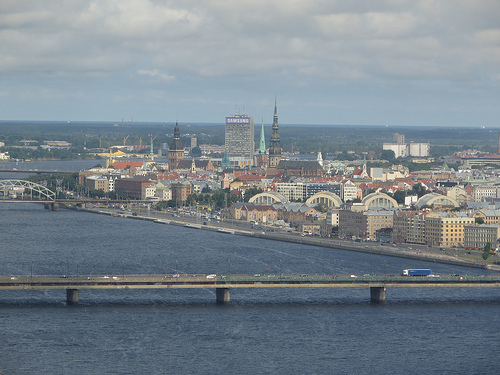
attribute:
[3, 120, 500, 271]
land — flat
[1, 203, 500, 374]
water — here, river, calm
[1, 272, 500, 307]
bridge — white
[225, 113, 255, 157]
building — tall, tallest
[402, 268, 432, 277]
truck — blue, white, large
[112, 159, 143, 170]
roof — red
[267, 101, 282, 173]
tower — tall, tallest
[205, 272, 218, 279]
car — white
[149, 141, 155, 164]
building — green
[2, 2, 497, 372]
picture — panoramic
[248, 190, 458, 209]
archways — yellow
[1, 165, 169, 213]
bridges — distant